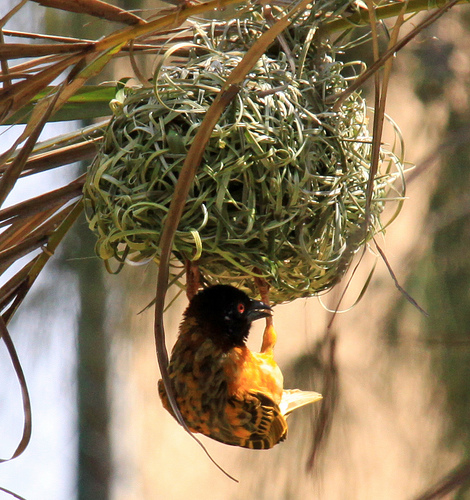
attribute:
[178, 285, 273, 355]
head — black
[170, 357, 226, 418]
feathers — speckled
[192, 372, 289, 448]
wing — black, yellow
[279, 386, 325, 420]
tail — yellow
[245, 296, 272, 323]
beak — black, pointed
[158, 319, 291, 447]
body — yellow, black, speckled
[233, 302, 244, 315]
eye — red, glassy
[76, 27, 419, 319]
ball — green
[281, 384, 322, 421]
tailfeather — yellow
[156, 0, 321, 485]
leaf — long, dry, brown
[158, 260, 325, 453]
bird — yellow, black, green, small, exotic, colorful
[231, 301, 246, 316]
eye — round, red, black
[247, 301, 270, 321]
beak — pointy, small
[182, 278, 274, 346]
head — small, feathered, black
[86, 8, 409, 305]
nest — green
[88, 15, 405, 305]
grass — clumped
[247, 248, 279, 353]
leg — yellow, skinny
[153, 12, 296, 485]
leaf — long, narrow, dry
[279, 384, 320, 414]
tail — wide, yellow, feathered